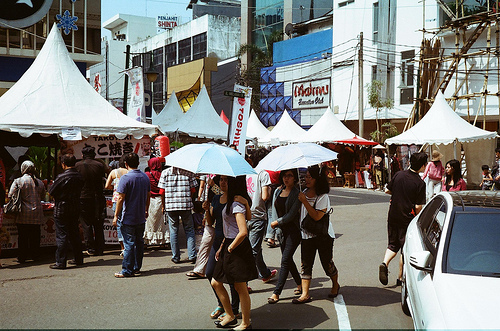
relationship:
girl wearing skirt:
[208, 173, 261, 328] [209, 237, 266, 291]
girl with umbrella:
[208, 173, 261, 328] [165, 141, 260, 186]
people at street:
[93, 147, 361, 313] [23, 277, 192, 331]